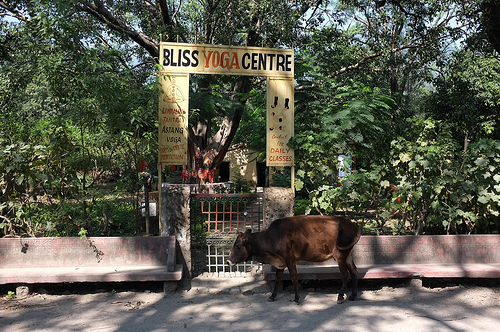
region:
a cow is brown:
[218, 202, 373, 309]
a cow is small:
[222, 207, 379, 312]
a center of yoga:
[142, 34, 311, 180]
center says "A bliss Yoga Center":
[155, 35, 302, 77]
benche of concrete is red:
[1, 230, 184, 300]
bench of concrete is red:
[272, 228, 497, 288]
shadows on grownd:
[20, 291, 499, 329]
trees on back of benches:
[3, 8, 497, 210]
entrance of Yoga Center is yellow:
[145, 36, 300, 188]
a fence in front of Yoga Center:
[186, 185, 261, 278]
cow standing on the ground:
[204, 196, 416, 306]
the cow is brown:
[239, 198, 397, 299]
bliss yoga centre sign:
[144, 25, 356, 110]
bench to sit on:
[8, 220, 193, 310]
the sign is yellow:
[136, 25, 307, 160]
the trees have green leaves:
[14, 28, 152, 248]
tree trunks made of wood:
[25, 104, 170, 279]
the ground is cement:
[43, 291, 308, 330]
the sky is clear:
[304, 6, 426, 46]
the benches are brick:
[32, 241, 204, 270]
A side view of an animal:
[211, 200, 371, 316]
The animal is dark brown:
[215, 203, 368, 313]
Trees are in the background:
[1, 5, 496, 218]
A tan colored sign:
[153, 33, 300, 169]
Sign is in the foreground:
[150, 33, 301, 171]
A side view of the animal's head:
[210, 191, 265, 286]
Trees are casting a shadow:
[5, 287, 495, 327]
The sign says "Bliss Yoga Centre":
[160, 35, 296, 80]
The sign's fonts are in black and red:
[155, 45, 296, 78]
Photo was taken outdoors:
[6, 5, 493, 330]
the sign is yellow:
[121, 23, 336, 260]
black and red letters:
[148, 27, 333, 83]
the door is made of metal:
[181, 177, 310, 284]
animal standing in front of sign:
[211, 194, 386, 324]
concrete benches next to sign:
[5, 195, 495, 288]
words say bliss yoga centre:
[159, 42, 294, 94]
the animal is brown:
[206, 192, 411, 317]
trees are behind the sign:
[3, 2, 488, 267]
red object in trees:
[380, 165, 416, 215]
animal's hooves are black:
[263, 270, 370, 315]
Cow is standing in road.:
[216, 201, 383, 313]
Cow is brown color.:
[227, 207, 387, 305]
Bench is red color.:
[1, 234, 181, 296]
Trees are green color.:
[11, 83, 102, 163]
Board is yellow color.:
[152, 42, 298, 164]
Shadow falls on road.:
[68, 263, 461, 323]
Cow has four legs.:
[257, 266, 369, 308]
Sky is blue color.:
[64, 19, 153, 71]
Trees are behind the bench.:
[31, 46, 437, 171]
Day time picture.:
[36, 18, 473, 313]